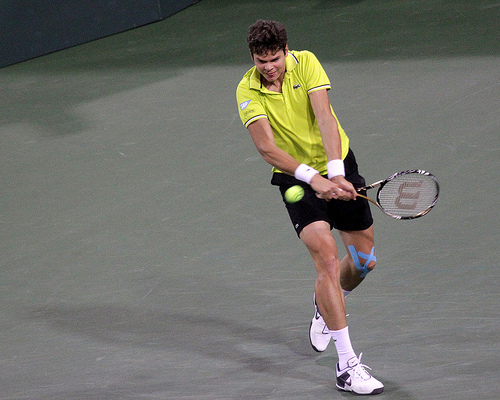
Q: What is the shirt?
A: Bright yellow.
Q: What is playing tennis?
A: The man.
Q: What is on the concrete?
A: The shadow of the man.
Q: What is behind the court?
A: Bluish gray tarp.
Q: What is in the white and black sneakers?
A: The man.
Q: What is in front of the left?
A: The right leg.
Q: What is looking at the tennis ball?
A: The man.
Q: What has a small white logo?
A: The black shorts.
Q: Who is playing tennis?
A: The man in the yellow shirt.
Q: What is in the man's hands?
A: A tennis racket.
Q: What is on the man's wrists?
A: Wristbands.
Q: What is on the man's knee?
A: Blue tape.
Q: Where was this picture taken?
A: At a tennis court.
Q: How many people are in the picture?
A: One.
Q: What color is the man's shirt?
A: Yellow.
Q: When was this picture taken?
A: During a tennis game.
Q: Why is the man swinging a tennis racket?
A: To hit the ball.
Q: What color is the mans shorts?
A: Black.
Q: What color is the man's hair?
A: Brown.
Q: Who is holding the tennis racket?
A: A man.